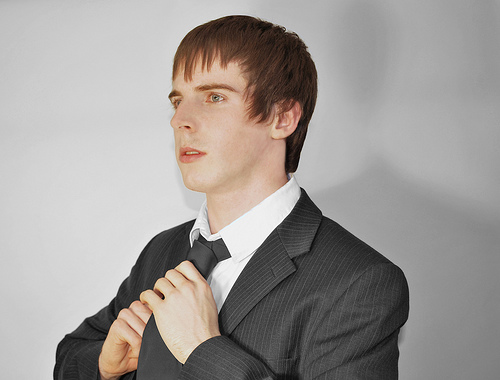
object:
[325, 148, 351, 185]
ground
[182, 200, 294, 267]
collar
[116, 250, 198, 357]
fingers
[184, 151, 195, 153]
teeth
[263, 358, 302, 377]
pocket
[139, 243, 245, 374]
necktie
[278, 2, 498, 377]
shadow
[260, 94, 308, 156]
ear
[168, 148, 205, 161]
mouth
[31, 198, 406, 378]
jacket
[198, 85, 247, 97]
eyebrow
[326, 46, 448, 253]
shadow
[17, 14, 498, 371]
wall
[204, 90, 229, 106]
eye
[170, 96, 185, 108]
eye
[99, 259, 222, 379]
hands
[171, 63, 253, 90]
forehead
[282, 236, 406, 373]
pin stripes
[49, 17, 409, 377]
man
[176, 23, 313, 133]
hair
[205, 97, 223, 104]
eye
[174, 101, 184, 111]
eye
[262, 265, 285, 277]
button hole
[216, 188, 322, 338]
lapel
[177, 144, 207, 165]
lips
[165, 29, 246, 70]
bangs